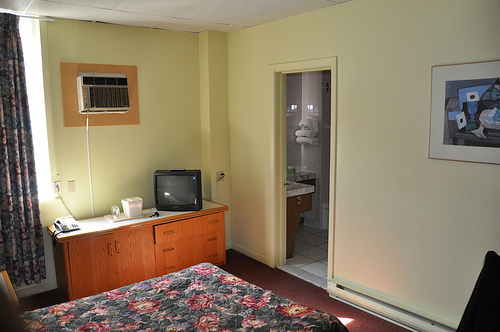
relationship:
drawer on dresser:
[150, 212, 226, 243] [48, 196, 227, 299]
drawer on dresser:
[153, 231, 225, 260] [48, 196, 227, 299]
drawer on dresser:
[157, 244, 227, 277] [48, 196, 227, 299]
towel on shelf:
[296, 128, 314, 140] [295, 133, 312, 138]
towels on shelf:
[296, 136, 322, 146] [299, 142, 314, 147]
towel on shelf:
[300, 112, 317, 129] [299, 123, 315, 127]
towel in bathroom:
[296, 128, 314, 140] [283, 69, 331, 286]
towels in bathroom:
[296, 136, 322, 146] [283, 69, 331, 286]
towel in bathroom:
[300, 112, 317, 129] [283, 69, 331, 286]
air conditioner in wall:
[76, 71, 139, 119] [19, 9, 232, 249]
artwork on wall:
[428, 60, 498, 169] [227, 1, 498, 330]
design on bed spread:
[1, 263, 349, 332] [11, 261, 349, 329]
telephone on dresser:
[56, 215, 79, 232] [48, 196, 227, 299]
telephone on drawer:
[47, 213, 82, 247] [47, 205, 232, 303]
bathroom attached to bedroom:
[273, 70, 329, 291] [0, 0, 498, 329]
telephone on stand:
[47, 213, 82, 247] [47, 227, 199, 262]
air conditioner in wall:
[59, 62, 138, 125] [6, 13, 237, 302]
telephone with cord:
[47, 213, 82, 247] [53, 197, 80, 220]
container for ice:
[111, 183, 163, 221] [129, 200, 142, 205]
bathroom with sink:
[273, 70, 329, 291] [288, 164, 309, 180]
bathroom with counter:
[273, 70, 329, 291] [288, 165, 320, 251]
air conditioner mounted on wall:
[76, 71, 139, 119] [25, 19, 230, 209]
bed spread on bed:
[11, 261, 349, 329] [2, 254, 356, 329]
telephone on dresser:
[47, 213, 82, 247] [48, 196, 227, 299]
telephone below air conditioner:
[47, 213, 82, 247] [78, 73, 132, 114]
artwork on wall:
[428, 60, 498, 169] [341, 17, 492, 322]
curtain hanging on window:
[0, 12, 48, 287] [1, 14, 58, 292]